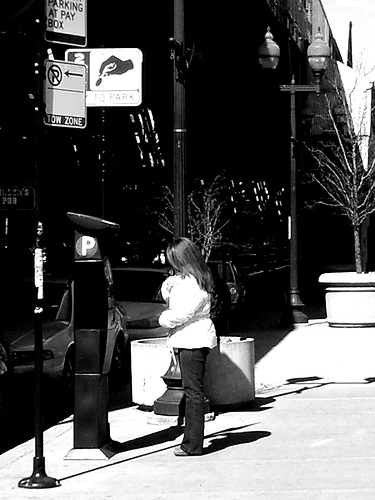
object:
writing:
[79, 236, 97, 258]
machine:
[63, 203, 119, 461]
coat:
[158, 272, 218, 353]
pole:
[168, 0, 189, 245]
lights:
[254, 27, 286, 74]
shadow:
[212, 372, 374, 415]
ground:
[0, 302, 375, 500]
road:
[0, 380, 375, 500]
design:
[95, 52, 135, 87]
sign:
[63, 44, 146, 109]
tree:
[300, 90, 375, 274]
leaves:
[328, 78, 336, 88]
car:
[7, 276, 130, 387]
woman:
[157, 236, 218, 457]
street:
[0, 225, 375, 382]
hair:
[166, 236, 221, 295]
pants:
[177, 348, 211, 457]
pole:
[32, 0, 46, 456]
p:
[79, 234, 99, 257]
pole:
[288, 77, 301, 294]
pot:
[315, 270, 375, 330]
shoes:
[172, 445, 203, 457]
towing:
[46, 113, 64, 128]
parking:
[47, 0, 87, 12]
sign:
[41, 57, 89, 130]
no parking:
[46, 64, 62, 86]